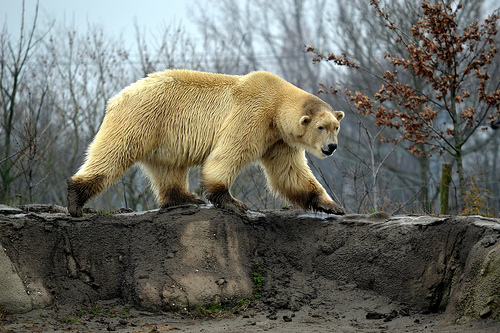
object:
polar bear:
[65, 68, 346, 217]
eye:
[317, 125, 325, 131]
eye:
[335, 127, 338, 131]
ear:
[298, 115, 312, 126]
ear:
[336, 111, 345, 122]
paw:
[309, 198, 347, 215]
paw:
[205, 189, 250, 212]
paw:
[158, 193, 206, 208]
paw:
[65, 175, 84, 219]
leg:
[260, 139, 335, 203]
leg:
[200, 134, 263, 223]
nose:
[329, 143, 338, 150]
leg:
[138, 162, 205, 210]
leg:
[56, 128, 137, 213]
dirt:
[1, 204, 499, 333]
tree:
[335, 0, 498, 217]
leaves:
[431, 0, 496, 130]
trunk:
[449, 87, 470, 214]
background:
[2, 1, 499, 204]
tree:
[2, 1, 57, 205]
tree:
[43, 12, 113, 174]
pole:
[438, 162, 453, 216]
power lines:
[2, 52, 387, 75]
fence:
[244, 163, 499, 216]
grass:
[82, 200, 115, 215]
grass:
[63, 297, 132, 324]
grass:
[195, 300, 245, 309]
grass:
[252, 261, 269, 300]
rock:
[281, 314, 292, 322]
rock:
[248, 320, 256, 327]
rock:
[216, 278, 226, 286]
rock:
[412, 317, 422, 324]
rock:
[119, 319, 127, 325]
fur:
[280, 189, 317, 206]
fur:
[206, 181, 231, 200]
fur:
[161, 185, 185, 197]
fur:
[73, 174, 106, 201]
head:
[299, 98, 343, 158]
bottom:
[67, 182, 77, 214]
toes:
[69, 209, 83, 217]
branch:
[345, 0, 496, 177]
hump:
[236, 71, 291, 87]